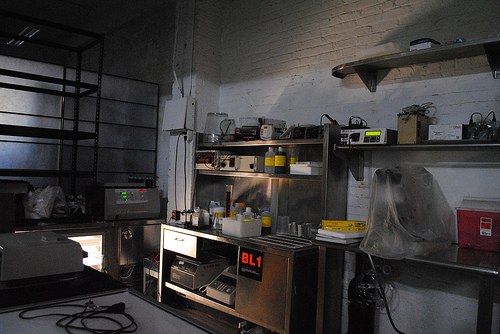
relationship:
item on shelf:
[406, 37, 442, 51] [329, 38, 499, 92]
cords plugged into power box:
[170, 132, 193, 213] [159, 58, 199, 131]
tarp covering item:
[365, 159, 455, 258] [372, 165, 434, 260]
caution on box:
[478, 216, 493, 237] [454, 195, 500, 255]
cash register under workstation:
[203, 262, 240, 302] [147, 104, 348, 334]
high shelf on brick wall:
[331, 35, 500, 94] [158, 0, 500, 334]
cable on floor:
[19, 297, 139, 332] [0, 282, 241, 332]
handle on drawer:
[173, 229, 190, 244] [155, 217, 204, 262]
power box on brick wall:
[159, 93, 199, 131] [158, 0, 500, 334]